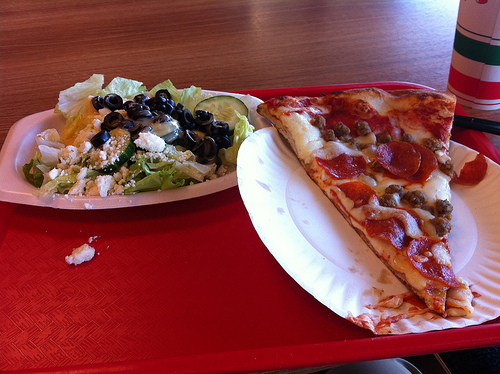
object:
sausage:
[378, 193, 399, 207]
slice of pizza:
[256, 87, 474, 319]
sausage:
[310, 115, 326, 128]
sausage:
[354, 119, 371, 136]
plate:
[236, 127, 500, 335]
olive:
[104, 93, 124, 112]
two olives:
[90, 112, 123, 147]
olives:
[192, 137, 215, 156]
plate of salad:
[0, 89, 274, 211]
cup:
[445, 0, 500, 111]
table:
[0, 0, 500, 153]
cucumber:
[193, 95, 248, 130]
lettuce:
[55, 73, 106, 127]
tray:
[1, 81, 500, 374]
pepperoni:
[378, 141, 422, 177]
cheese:
[134, 132, 166, 154]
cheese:
[65, 236, 100, 265]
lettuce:
[152, 77, 210, 116]